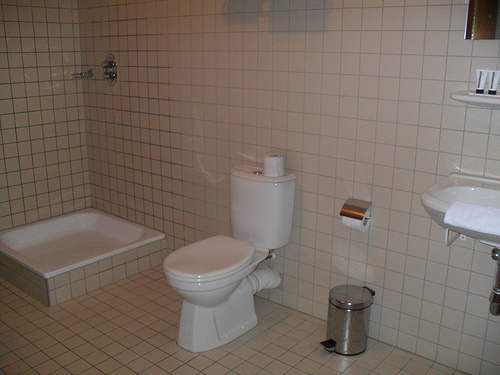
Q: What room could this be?
A: It is a bathroom.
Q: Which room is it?
A: It is a bathroom.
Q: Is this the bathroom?
A: Yes, it is the bathroom.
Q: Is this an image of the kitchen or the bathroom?
A: It is showing the bathroom.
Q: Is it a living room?
A: No, it is a bathroom.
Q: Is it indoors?
A: Yes, it is indoors.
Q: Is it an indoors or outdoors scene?
A: It is indoors.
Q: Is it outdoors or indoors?
A: It is indoors.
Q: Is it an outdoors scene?
A: No, it is indoors.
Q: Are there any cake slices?
A: No, there are no cake slices.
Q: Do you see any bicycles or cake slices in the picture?
A: No, there are no cake slices or bicycles.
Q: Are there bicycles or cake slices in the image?
A: No, there are no cake slices or bicycles.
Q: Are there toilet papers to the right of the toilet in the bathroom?
A: Yes, there is a toilet paper to the right of the toilet.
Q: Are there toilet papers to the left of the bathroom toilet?
A: No, the toilet paper is to the right of the toilet.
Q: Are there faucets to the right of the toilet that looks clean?
A: No, there is a toilet paper to the right of the toilet.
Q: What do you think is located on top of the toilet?
A: The toilet paper is on top of the toilet.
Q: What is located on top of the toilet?
A: The toilet paper is on top of the toilet.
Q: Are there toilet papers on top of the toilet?
A: Yes, there is a toilet paper on top of the toilet.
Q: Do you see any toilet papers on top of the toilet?
A: Yes, there is a toilet paper on top of the toilet.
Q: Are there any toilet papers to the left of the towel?
A: Yes, there is a toilet paper to the left of the towel.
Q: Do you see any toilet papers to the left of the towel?
A: Yes, there is a toilet paper to the left of the towel.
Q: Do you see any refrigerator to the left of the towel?
A: No, there is a toilet paper to the left of the towel.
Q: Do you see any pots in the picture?
A: No, there are no pots.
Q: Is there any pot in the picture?
A: No, there are no pots.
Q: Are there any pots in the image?
A: No, there are no pots.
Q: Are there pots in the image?
A: No, there are no pots.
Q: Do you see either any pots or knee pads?
A: No, there are no pots or knee pads.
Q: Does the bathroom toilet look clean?
A: Yes, the toilet is clean.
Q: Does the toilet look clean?
A: Yes, the toilet is clean.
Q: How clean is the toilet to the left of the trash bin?
A: The toilet is clean.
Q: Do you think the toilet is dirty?
A: No, the toilet is clean.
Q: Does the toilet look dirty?
A: No, the toilet is clean.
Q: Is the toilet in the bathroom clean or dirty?
A: The toilet is clean.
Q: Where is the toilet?
A: The toilet is in the bathroom.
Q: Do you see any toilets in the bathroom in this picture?
A: Yes, there is a toilet in the bathroom.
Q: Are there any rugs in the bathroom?
A: No, there is a toilet in the bathroom.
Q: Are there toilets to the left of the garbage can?
A: Yes, there is a toilet to the left of the garbage can.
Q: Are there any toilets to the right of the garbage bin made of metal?
A: No, the toilet is to the left of the trashcan.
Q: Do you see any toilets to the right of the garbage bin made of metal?
A: No, the toilet is to the left of the trashcan.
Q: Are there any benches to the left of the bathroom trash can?
A: No, there is a toilet to the left of the trash bin.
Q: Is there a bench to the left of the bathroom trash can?
A: No, there is a toilet to the left of the trash bin.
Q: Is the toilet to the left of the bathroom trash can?
A: Yes, the toilet is to the left of the trashcan.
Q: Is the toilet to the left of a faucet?
A: No, the toilet is to the left of the trashcan.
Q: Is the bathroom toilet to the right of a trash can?
A: No, the toilet is to the left of a trash can.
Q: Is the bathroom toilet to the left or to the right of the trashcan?
A: The toilet is to the left of the trashcan.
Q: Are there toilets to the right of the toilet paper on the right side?
A: No, the toilet is to the left of the toilet paper.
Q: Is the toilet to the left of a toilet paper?
A: Yes, the toilet is to the left of a toilet paper.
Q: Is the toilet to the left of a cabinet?
A: No, the toilet is to the left of a toilet paper.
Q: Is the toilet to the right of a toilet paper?
A: No, the toilet is to the left of a toilet paper.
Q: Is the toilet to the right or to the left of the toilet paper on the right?
A: The toilet is to the left of the toilet paper.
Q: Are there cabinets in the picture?
A: No, there are no cabinets.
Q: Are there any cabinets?
A: No, there are no cabinets.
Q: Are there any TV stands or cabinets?
A: No, there are no cabinets or TV stands.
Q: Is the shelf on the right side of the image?
A: Yes, the shelf is on the right of the image.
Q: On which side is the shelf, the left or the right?
A: The shelf is on the right of the image.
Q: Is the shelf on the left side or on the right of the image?
A: The shelf is on the right of the image.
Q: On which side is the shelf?
A: The shelf is on the right of the image.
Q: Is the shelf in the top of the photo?
A: Yes, the shelf is in the top of the image.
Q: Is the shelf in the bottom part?
A: No, the shelf is in the top of the image.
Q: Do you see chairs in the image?
A: No, there are no chairs.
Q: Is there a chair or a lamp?
A: No, there are no chairs or lamps.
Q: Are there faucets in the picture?
A: No, there are no faucets.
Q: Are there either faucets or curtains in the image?
A: No, there are no faucets or curtains.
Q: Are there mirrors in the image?
A: Yes, there is a mirror.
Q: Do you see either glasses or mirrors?
A: Yes, there is a mirror.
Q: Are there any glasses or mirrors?
A: Yes, there is a mirror.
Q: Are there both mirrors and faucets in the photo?
A: No, there is a mirror but no faucets.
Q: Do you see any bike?
A: No, there are no bikes.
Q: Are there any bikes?
A: No, there are no bikes.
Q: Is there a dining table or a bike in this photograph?
A: No, there are no bikes or dining tables.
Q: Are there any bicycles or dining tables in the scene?
A: No, there are no bicycles or dining tables.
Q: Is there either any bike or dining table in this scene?
A: No, there are no bikes or dining tables.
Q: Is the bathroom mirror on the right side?
A: Yes, the mirror is on the right of the image.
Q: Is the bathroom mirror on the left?
A: No, the mirror is on the right of the image.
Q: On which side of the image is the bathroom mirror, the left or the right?
A: The mirror is on the right of the image.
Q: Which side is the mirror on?
A: The mirror is on the right of the image.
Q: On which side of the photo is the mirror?
A: The mirror is on the right of the image.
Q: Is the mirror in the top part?
A: Yes, the mirror is in the top of the image.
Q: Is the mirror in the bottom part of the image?
A: No, the mirror is in the top of the image.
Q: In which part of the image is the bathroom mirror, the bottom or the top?
A: The mirror is in the top of the image.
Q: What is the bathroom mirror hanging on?
A: The mirror is hanging on the wall.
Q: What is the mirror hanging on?
A: The mirror is hanging on the wall.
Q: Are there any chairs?
A: No, there are no chairs.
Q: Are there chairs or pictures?
A: No, there are no chairs or pictures.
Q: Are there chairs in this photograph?
A: No, there are no chairs.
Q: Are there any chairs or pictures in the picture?
A: No, there are no chairs or pictures.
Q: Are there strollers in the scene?
A: No, there are no strollers.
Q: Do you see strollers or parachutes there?
A: No, there are no strollers or parachutes.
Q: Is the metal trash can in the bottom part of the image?
A: Yes, the garbage can is in the bottom of the image.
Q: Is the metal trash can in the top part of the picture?
A: No, the trashcan is in the bottom of the image.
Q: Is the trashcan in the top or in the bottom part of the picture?
A: The trashcan is in the bottom of the image.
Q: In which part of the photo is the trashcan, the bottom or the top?
A: The trashcan is in the bottom of the image.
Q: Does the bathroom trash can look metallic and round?
A: Yes, the trash can is metallic and round.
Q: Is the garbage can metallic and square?
A: No, the garbage can is metallic but round.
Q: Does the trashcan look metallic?
A: Yes, the trashcan is metallic.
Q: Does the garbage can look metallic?
A: Yes, the garbage can is metallic.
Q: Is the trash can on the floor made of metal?
A: Yes, the garbage bin is made of metal.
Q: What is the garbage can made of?
A: The garbage can is made of metal.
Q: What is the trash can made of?
A: The garbage can is made of metal.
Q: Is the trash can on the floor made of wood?
A: No, the garbage can is made of metal.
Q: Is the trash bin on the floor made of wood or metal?
A: The garbage can is made of metal.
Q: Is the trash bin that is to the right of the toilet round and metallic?
A: Yes, the trashcan is round and metallic.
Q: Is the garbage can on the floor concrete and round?
A: No, the trash can is round but metallic.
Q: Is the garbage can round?
A: Yes, the garbage can is round.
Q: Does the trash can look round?
A: Yes, the trash can is round.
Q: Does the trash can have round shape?
A: Yes, the trash can is round.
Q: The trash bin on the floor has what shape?
A: The garbage can is round.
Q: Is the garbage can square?
A: No, the garbage can is round.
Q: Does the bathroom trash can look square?
A: No, the garbage can is round.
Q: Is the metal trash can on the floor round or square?
A: The trashcan is round.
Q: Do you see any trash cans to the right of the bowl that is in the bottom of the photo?
A: Yes, there is a trash can to the right of the bowl.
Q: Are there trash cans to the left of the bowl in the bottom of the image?
A: No, the trash can is to the right of the bowl.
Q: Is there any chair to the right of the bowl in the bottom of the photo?
A: No, there is a trash can to the right of the bowl.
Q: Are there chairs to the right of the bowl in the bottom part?
A: No, there is a trash can to the right of the bowl.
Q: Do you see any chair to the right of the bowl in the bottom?
A: No, there is a trash can to the right of the bowl.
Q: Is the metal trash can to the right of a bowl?
A: Yes, the garbage can is to the right of a bowl.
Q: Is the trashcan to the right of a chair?
A: No, the trashcan is to the right of a bowl.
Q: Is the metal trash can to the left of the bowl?
A: No, the garbage can is to the right of the bowl.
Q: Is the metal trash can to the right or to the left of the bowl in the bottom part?
A: The garbage can is to the right of the bowl.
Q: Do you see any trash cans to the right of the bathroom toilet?
A: Yes, there is a trash can to the right of the toilet.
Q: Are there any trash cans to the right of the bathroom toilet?
A: Yes, there is a trash can to the right of the toilet.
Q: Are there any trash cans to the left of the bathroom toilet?
A: No, the trash can is to the right of the toilet.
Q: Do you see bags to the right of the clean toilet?
A: No, there is a trash can to the right of the toilet.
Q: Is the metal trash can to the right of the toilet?
A: Yes, the garbage bin is to the right of the toilet.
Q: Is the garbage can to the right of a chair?
A: No, the garbage can is to the right of the toilet.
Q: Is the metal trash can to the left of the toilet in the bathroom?
A: No, the trash can is to the right of the toilet.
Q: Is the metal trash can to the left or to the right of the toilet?
A: The trash can is to the right of the toilet.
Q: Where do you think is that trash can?
A: The trash can is on the floor.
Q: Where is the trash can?
A: The trash can is on the floor.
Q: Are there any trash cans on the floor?
A: Yes, there is a trash can on the floor.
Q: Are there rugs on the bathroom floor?
A: No, there is a trash can on the floor.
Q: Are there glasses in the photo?
A: No, there are no glasses.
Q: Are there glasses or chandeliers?
A: No, there are no glasses or chandeliers.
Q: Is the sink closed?
A: Yes, the sink is closed.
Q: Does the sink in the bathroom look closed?
A: Yes, the sink is closed.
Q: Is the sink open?
A: No, the sink is closed.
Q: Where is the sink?
A: The sink is in the bathroom.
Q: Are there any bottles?
A: Yes, there is a bottle.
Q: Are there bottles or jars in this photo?
A: Yes, there is a bottle.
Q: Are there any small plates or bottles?
A: Yes, there is a small bottle.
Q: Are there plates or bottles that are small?
A: Yes, the bottle is small.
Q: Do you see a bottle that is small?
A: Yes, there is a small bottle.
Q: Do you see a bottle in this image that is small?
A: Yes, there is a bottle that is small.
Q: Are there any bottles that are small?
A: Yes, there is a bottle that is small.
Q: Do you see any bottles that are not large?
A: Yes, there is a small bottle.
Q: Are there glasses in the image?
A: No, there are no glasses.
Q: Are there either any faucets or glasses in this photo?
A: No, there are no glasses or faucets.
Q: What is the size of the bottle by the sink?
A: The bottle is small.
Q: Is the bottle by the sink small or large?
A: The bottle is small.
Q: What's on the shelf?
A: The bottle is on the shelf.